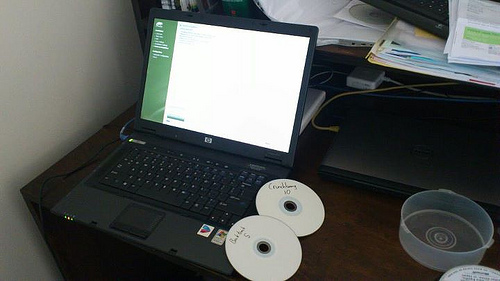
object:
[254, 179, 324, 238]
cd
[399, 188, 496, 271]
cd case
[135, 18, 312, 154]
screen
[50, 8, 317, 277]
laptop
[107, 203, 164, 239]
trackpad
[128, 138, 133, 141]
lights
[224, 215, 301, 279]
discs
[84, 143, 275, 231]
keyboard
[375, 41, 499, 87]
papers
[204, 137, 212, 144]
logo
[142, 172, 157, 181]
keys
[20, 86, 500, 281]
table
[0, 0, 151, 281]
wall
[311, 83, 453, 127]
cords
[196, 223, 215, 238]
stickers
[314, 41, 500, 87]
shelf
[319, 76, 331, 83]
wire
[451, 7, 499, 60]
books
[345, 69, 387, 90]
box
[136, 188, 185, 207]
space bar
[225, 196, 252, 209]
enter key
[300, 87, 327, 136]
router